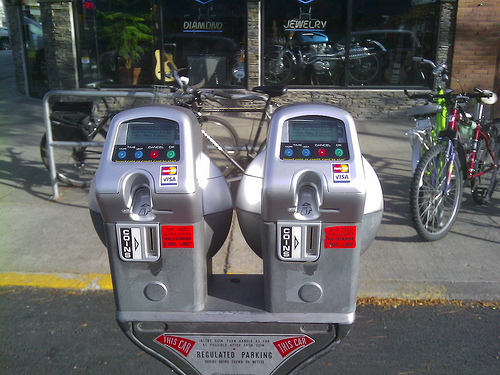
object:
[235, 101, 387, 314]
metal parking meter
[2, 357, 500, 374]
curb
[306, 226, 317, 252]
coin slot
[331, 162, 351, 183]
credit card logo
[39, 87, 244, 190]
bike rack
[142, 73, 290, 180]
bicycle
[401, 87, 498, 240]
bicycle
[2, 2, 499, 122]
store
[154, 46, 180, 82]
guitar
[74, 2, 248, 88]
store window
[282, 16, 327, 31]
neon sign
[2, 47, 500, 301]
sidewalk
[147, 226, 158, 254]
coin slot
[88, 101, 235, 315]
parking meter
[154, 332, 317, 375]
sign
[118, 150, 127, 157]
button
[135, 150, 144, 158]
button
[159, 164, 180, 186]
credit card logo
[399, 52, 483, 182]
bicycles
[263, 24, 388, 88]
motorcycle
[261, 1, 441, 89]
store window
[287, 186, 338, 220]
credit card slot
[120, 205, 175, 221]
credit card slot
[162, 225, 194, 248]
sticker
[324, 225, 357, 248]
sign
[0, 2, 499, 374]
street scene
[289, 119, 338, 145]
digital display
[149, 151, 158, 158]
button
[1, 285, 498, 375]
street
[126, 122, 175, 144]
digital display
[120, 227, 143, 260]
sticker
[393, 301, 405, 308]
leaves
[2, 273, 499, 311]
curb